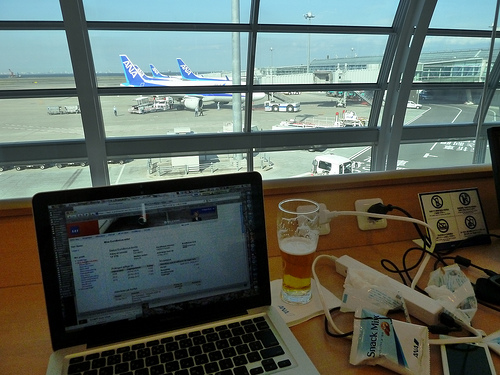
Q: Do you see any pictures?
A: No, there are no pictures.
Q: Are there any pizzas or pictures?
A: No, there are no pictures or pizzas.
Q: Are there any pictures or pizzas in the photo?
A: No, there are no pictures or pizzas.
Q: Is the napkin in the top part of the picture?
A: No, the napkin is in the bottom of the image.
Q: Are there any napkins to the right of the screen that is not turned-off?
A: Yes, there is a napkin to the right of the screen.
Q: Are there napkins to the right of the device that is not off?
A: Yes, there is a napkin to the right of the screen.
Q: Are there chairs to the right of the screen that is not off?
A: No, there is a napkin to the right of the screen.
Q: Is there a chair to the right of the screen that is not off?
A: No, there is a napkin to the right of the screen.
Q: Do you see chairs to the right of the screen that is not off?
A: No, there is a napkin to the right of the screen.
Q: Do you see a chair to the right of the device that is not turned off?
A: No, there is a napkin to the right of the screen.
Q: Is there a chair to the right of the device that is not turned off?
A: No, there is a napkin to the right of the screen.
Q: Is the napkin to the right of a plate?
A: No, the napkin is to the right of the screen.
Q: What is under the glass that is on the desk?
A: The napkin is under the glass.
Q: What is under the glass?
A: The napkin is under the glass.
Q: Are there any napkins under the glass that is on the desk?
A: Yes, there is a napkin under the glass.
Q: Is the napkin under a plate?
A: No, the napkin is under a glass.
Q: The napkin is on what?
A: The napkin is on the desk.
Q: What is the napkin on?
A: The napkin is on the desk.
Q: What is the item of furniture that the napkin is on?
A: The piece of furniture is a desk.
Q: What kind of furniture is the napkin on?
A: The napkin is on the desk.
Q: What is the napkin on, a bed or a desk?
A: The napkin is on a desk.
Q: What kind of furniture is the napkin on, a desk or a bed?
A: The napkin is on a desk.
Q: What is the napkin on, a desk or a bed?
A: The napkin is on a desk.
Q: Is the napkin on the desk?
A: Yes, the napkin is on the desk.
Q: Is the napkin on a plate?
A: No, the napkin is on the desk.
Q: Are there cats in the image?
A: No, there are no cats.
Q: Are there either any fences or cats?
A: No, there are no cats or fences.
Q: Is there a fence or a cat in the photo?
A: No, there are no cats or fences.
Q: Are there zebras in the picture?
A: No, there are no zebras.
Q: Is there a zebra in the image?
A: No, there are no zebras.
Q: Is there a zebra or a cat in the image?
A: No, there are no zebras or cats.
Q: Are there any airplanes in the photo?
A: Yes, there is an airplane.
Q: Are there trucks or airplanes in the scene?
A: Yes, there is an airplane.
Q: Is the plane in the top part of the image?
A: Yes, the plane is in the top of the image.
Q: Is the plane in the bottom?
A: No, the plane is in the top of the image.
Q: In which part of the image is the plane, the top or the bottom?
A: The plane is in the top of the image.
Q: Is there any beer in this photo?
A: Yes, there is beer.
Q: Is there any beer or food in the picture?
A: Yes, there is beer.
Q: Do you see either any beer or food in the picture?
A: Yes, there is beer.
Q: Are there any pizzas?
A: No, there are no pizzas.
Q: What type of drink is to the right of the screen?
A: The drink is beer.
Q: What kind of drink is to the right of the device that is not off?
A: The drink is beer.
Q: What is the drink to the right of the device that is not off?
A: The drink is beer.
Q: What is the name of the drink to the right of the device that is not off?
A: The drink is beer.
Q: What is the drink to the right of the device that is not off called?
A: The drink is beer.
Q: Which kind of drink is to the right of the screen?
A: The drink is beer.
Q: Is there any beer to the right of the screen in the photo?
A: Yes, there is beer to the right of the screen.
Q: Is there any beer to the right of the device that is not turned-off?
A: Yes, there is beer to the right of the screen.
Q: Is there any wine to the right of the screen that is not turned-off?
A: No, there is beer to the right of the screen.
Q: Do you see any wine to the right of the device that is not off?
A: No, there is beer to the right of the screen.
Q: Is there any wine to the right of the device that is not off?
A: No, there is beer to the right of the screen.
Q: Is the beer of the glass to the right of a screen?
A: Yes, the beer is to the right of a screen.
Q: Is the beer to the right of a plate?
A: No, the beer is to the right of a screen.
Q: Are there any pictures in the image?
A: No, there are no pictures.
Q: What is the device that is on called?
A: The device is a screen.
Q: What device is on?
A: The device is a screen.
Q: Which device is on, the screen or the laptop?
A: The screen is on.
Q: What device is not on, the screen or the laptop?
A: The laptop is not on.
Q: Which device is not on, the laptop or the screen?
A: The laptop is not on.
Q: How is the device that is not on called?
A: The device is a laptop.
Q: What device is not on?
A: The device is a laptop.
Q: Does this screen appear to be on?
A: Yes, the screen is on.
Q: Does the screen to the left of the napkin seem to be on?
A: Yes, the screen is on.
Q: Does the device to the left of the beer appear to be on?
A: Yes, the screen is on.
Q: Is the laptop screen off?
A: No, the screen is on.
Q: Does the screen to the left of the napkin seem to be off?
A: No, the screen is on.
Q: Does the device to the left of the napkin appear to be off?
A: No, the screen is on.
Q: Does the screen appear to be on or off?
A: The screen is on.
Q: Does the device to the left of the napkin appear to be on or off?
A: The screen is on.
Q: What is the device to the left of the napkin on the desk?
A: The device is a screen.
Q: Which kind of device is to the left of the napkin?
A: The device is a screen.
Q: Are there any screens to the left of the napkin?
A: Yes, there is a screen to the left of the napkin.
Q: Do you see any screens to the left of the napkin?
A: Yes, there is a screen to the left of the napkin.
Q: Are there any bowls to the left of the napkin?
A: No, there is a screen to the left of the napkin.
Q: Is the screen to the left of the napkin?
A: Yes, the screen is to the left of the napkin.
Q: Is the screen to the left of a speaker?
A: No, the screen is to the left of the napkin.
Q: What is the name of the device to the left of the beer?
A: The device is a screen.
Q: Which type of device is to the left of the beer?
A: The device is a screen.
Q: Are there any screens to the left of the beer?
A: Yes, there is a screen to the left of the beer.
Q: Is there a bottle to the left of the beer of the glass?
A: No, there is a screen to the left of the beer.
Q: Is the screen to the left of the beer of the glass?
A: Yes, the screen is to the left of the beer.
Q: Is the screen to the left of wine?
A: No, the screen is to the left of the beer.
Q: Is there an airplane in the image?
A: Yes, there is an airplane.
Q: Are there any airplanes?
A: Yes, there is an airplane.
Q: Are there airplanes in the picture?
A: Yes, there is an airplane.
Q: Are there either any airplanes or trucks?
A: Yes, there is an airplane.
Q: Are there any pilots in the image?
A: No, there are no pilots.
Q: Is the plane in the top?
A: Yes, the plane is in the top of the image.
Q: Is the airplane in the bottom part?
A: No, the airplane is in the top of the image.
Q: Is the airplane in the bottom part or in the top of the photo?
A: The airplane is in the top of the image.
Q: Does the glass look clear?
A: Yes, the glass is clear.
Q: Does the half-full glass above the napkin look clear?
A: Yes, the glass is clear.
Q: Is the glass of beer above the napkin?
A: Yes, the glass is above the napkin.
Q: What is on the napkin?
A: The glass is on the napkin.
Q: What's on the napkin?
A: The glass is on the napkin.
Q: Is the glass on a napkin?
A: Yes, the glass is on a napkin.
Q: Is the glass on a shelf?
A: No, the glass is on a napkin.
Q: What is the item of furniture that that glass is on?
A: The piece of furniture is a desk.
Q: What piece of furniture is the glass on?
A: The glass is on the desk.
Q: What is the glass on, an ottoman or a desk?
A: The glass is on a desk.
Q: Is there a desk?
A: Yes, there is a desk.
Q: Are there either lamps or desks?
A: Yes, there is a desk.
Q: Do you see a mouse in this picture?
A: No, there are no computer mice.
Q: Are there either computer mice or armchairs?
A: No, there are no computer mice or armchairs.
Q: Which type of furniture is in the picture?
A: The furniture is a desk.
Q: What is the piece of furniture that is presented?
A: The piece of furniture is a desk.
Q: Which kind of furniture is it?
A: The piece of furniture is a desk.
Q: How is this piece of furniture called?
A: This is a desk.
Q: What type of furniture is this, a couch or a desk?
A: This is a desk.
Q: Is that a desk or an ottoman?
A: That is a desk.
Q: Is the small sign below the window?
A: Yes, the sign is below the window.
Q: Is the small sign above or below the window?
A: The sign is below the window.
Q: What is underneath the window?
A: The sign is underneath the window.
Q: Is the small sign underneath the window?
A: Yes, the sign is underneath the window.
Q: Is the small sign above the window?
A: No, the sign is underneath the window.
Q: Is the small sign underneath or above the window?
A: The sign is underneath the window.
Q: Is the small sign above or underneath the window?
A: The sign is underneath the window.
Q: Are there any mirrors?
A: No, there are no mirrors.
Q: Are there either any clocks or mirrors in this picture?
A: No, there are no mirrors or clocks.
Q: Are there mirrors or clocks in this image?
A: No, there are no mirrors or clocks.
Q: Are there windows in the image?
A: Yes, there is a window.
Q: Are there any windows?
A: Yes, there is a window.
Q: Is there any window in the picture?
A: Yes, there is a window.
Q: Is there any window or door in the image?
A: Yes, there is a window.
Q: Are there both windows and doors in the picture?
A: No, there is a window but no doors.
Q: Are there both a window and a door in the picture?
A: No, there is a window but no doors.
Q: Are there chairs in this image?
A: No, there are no chairs.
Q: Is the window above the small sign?
A: Yes, the window is above the sign.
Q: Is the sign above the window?
A: No, the window is above the sign.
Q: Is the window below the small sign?
A: No, the window is above the sign.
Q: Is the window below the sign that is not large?
A: No, the window is above the sign.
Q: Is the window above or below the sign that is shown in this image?
A: The window is above the sign.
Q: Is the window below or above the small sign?
A: The window is above the sign.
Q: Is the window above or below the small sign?
A: The window is above the sign.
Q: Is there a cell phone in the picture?
A: Yes, there is a cell phone.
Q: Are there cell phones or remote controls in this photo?
A: Yes, there is a cell phone.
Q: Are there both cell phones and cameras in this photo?
A: No, there is a cell phone but no cameras.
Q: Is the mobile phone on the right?
A: Yes, the mobile phone is on the right of the image.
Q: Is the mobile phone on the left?
A: No, the mobile phone is on the right of the image.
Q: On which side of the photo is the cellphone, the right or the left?
A: The cellphone is on the right of the image.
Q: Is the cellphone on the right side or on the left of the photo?
A: The cellphone is on the right of the image.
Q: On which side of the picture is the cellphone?
A: The cellphone is on the right of the image.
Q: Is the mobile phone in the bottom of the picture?
A: Yes, the mobile phone is in the bottom of the image.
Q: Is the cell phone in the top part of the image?
A: No, the cell phone is in the bottom of the image.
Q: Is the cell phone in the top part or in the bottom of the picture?
A: The cell phone is in the bottom of the image.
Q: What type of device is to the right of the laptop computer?
A: The device is a cell phone.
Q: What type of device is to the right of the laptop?
A: The device is a cell phone.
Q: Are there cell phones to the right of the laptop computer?
A: Yes, there is a cell phone to the right of the laptop computer.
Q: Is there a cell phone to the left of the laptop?
A: No, the cell phone is to the right of the laptop.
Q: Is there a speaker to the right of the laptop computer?
A: No, there is a cell phone to the right of the laptop computer.